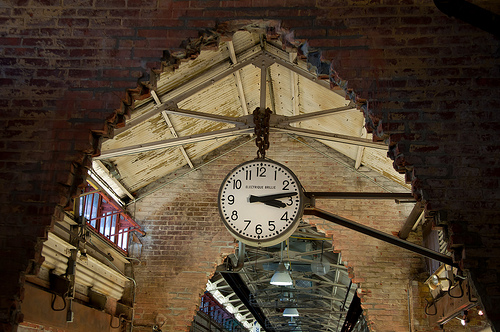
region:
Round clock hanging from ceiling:
[215, 158, 307, 246]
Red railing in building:
[74, 190, 138, 252]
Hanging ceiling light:
[264, 265, 296, 290]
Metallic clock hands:
[246, 189, 301, 209]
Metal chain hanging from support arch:
[249, 105, 273, 160]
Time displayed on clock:
[247, 188, 299, 213]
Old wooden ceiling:
[102, 30, 411, 192]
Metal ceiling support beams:
[96, 38, 391, 158]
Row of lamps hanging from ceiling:
[267, 258, 302, 328]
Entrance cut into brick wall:
[181, 220, 375, 328]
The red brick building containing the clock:
[8, 3, 113, 158]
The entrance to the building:
[77, 20, 472, 330]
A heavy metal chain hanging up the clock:
[242, 97, 290, 166]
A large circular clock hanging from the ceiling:
[222, 161, 307, 239]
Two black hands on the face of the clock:
[246, 185, 303, 213]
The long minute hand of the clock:
[248, 186, 303, 201]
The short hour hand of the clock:
[250, 195, 291, 211]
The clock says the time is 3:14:
[234, 172, 296, 230]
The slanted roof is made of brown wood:
[119, 49, 241, 179]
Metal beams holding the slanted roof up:
[121, 40, 390, 158]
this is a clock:
[218, 149, 302, 243]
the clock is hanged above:
[224, 149, 309, 239]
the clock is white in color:
[240, 202, 263, 219]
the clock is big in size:
[212, 157, 309, 238]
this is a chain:
[248, 105, 273, 157]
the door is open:
[60, 20, 452, 330]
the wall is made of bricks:
[388, 22, 474, 119]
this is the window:
[95, 199, 137, 238]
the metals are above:
[186, 102, 342, 138]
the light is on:
[268, 265, 293, 286]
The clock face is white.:
[216, 157, 305, 247]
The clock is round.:
[219, 158, 304, 248]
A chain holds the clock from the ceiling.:
[251, 103, 273, 160]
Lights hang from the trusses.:
[268, 264, 300, 316]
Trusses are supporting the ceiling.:
[97, 47, 389, 156]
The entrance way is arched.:
[186, 217, 369, 330]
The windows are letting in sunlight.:
[78, 172, 132, 251]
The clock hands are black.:
[248, 188, 299, 209]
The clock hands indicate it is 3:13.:
[248, 188, 298, 208]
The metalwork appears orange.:
[83, 181, 145, 252]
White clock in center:
[212, 148, 335, 245]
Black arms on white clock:
[230, 178, 330, 218]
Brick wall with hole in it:
[116, 97, 406, 324]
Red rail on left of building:
[65, 183, 152, 246]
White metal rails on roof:
[144, 82, 449, 157]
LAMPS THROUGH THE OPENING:
[266, 263, 317, 330]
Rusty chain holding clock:
[241, 97, 288, 159]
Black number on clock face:
[227, 160, 309, 246]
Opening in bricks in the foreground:
[16, 25, 456, 322]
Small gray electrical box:
[66, 299, 90, 326]